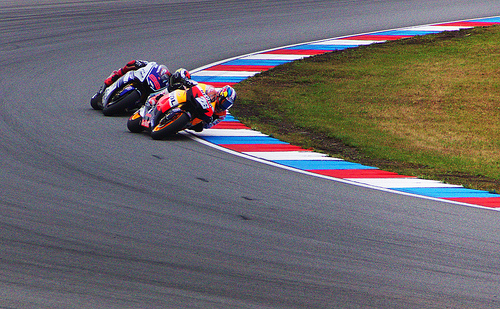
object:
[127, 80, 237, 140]
motorcycle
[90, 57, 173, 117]
motorcycle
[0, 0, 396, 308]
track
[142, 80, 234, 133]
biker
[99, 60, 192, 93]
biker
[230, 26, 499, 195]
grass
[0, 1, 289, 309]
race track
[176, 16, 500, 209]
red/white/blue stripe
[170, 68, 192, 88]
helmet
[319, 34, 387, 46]
stripe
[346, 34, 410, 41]
stripe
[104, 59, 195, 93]
person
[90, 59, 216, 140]
motorcycle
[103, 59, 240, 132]
biker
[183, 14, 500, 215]
stripe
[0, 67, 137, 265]
track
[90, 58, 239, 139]
train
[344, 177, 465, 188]
white stripe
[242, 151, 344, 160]
white stripe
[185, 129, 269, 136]
white stripe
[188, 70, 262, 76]
white stripe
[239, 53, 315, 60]
white stripe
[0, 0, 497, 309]
race track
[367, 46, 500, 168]
sand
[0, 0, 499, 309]
road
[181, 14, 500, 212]
white line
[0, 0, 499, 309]
track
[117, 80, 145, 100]
fender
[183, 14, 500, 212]
colors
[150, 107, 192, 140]
tire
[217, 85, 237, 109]
helmet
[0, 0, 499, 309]
pavement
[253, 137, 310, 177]
stripes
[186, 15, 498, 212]
red blue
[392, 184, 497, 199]
stripe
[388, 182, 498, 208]
stripe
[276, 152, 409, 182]
stripe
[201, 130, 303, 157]
stripe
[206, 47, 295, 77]
stripe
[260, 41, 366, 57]
stripe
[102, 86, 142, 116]
front tire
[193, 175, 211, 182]
mark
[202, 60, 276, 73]
stripe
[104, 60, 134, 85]
pant leg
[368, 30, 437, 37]
stripe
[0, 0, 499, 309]
curve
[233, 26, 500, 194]
tire tracks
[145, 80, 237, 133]
person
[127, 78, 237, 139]
bike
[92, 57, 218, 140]
bike